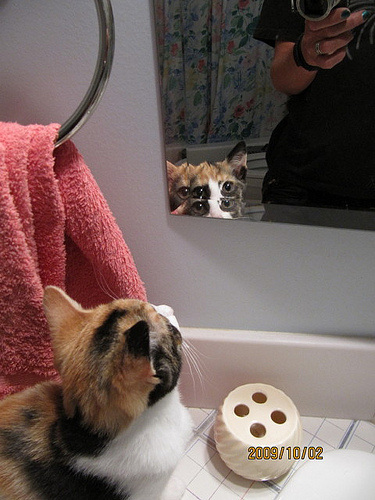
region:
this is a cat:
[13, 253, 229, 497]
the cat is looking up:
[13, 251, 217, 492]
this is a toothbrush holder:
[193, 348, 309, 498]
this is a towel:
[0, 105, 168, 423]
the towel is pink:
[6, 110, 172, 404]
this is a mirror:
[148, 8, 373, 246]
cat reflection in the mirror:
[150, 117, 279, 244]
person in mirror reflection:
[236, 5, 374, 225]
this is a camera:
[283, 3, 374, 54]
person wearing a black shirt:
[263, 4, 374, 192]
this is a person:
[214, 8, 363, 234]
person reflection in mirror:
[238, 1, 368, 243]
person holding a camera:
[259, 1, 372, 71]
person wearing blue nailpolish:
[328, 2, 370, 55]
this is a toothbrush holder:
[195, 350, 330, 485]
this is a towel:
[0, 86, 169, 444]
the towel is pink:
[0, 105, 176, 416]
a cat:
[177, 154, 265, 212]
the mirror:
[278, 118, 357, 200]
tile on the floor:
[205, 479, 236, 499]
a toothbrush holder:
[227, 389, 298, 442]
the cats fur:
[73, 400, 155, 481]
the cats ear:
[124, 310, 162, 352]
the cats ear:
[41, 287, 78, 321]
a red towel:
[8, 198, 66, 284]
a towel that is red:
[10, 152, 59, 241]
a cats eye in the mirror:
[219, 176, 235, 193]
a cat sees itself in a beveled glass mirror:
[164, 145, 255, 214]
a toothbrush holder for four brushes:
[212, 373, 300, 479]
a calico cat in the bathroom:
[0, 284, 195, 498]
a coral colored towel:
[0, 121, 138, 396]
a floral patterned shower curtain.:
[153, 3, 285, 144]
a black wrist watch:
[285, 41, 319, 84]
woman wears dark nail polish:
[331, 5, 373, 23]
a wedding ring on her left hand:
[312, 36, 324, 57]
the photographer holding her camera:
[275, 1, 373, 67]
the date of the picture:
[248, 443, 326, 462]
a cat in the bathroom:
[50, 267, 272, 450]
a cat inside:
[25, 252, 343, 497]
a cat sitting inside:
[3, 270, 297, 474]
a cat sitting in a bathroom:
[63, 248, 314, 468]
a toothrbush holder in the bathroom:
[183, 364, 361, 498]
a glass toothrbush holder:
[192, 353, 360, 497]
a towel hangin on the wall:
[11, 142, 184, 323]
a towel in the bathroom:
[22, 157, 202, 362]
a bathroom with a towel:
[21, 176, 182, 328]